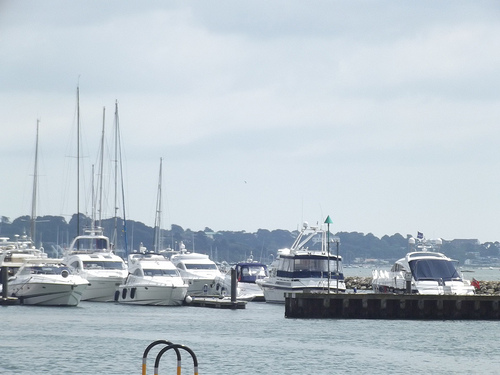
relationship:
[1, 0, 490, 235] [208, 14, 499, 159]
sky has clouds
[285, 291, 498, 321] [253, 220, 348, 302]
dock has boat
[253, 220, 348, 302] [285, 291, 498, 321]
boat on dock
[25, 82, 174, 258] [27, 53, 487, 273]
post in background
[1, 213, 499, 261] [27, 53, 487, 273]
trees in background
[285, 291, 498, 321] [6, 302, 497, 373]
dock in lake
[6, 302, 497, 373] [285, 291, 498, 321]
lake has dock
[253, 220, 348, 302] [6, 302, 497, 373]
boat in lake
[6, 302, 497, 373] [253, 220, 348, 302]
lake has boat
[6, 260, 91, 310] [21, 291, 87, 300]
boat has stripe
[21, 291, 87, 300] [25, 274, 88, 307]
stripe on front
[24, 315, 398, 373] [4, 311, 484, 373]
ripples in water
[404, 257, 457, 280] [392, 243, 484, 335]
front window of boat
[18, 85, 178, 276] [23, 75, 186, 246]
these are boat masts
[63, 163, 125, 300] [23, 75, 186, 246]
boat are boat masts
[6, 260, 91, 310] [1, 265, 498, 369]
boat are in water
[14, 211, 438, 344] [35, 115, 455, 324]
these are  boats seen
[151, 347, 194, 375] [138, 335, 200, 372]
portion of hand rails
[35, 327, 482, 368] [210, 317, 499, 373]
line in water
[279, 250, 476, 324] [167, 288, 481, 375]
asphalt railing on dock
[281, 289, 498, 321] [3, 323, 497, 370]
dock over water